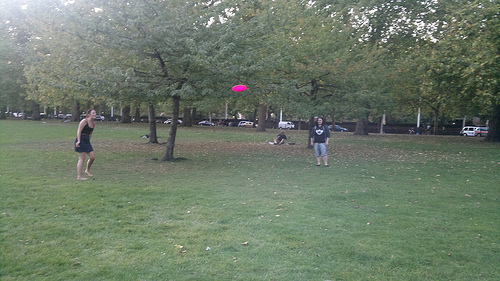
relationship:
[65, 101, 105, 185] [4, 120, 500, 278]
girl above grass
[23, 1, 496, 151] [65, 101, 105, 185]
trees above girl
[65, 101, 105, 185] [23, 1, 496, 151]
girl under trees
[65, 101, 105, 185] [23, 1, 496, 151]
girl below trees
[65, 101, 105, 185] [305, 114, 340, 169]
girl near woman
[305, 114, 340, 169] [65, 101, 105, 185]
woman near girl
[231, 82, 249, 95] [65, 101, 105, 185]
frisbee near girl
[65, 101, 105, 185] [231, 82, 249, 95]
girl near frisbee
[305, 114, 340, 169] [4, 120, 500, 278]
woman above grass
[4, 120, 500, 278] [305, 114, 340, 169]
grass under woman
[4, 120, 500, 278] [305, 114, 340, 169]
grass below woman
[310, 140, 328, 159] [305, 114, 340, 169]
shorts on woman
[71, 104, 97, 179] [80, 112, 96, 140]
woman wearing top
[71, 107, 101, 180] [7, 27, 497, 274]
girl in park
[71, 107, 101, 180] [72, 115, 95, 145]
girl in top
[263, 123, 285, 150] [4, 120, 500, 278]
person sitting in grass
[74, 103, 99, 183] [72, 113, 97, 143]
person in shirt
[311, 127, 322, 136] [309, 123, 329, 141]
symbol on shirt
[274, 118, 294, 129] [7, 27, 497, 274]
van by park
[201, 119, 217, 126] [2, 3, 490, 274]
car by park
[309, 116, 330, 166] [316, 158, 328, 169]
person with shoes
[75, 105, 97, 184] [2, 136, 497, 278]
man standing in lawn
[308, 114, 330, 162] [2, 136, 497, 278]
lady standing in lawn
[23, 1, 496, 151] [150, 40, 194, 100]
trees with branches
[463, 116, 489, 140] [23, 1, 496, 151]
car parked under trees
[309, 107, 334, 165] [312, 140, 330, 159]
man wearing half-trouser